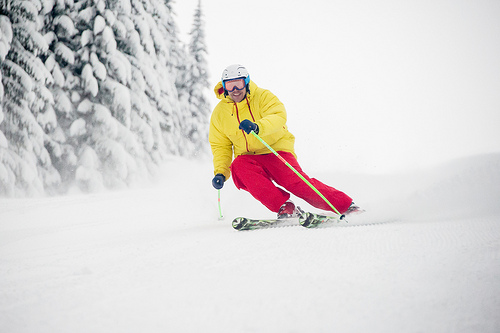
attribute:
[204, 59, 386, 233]
man — skier, standing, skiing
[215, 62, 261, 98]
helmet — white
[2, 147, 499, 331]
snow — white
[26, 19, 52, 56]
snow — white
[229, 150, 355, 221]
pants — red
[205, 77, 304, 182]
sweatshirt — yellow, hooded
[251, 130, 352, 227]
ski pole — neon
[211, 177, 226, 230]
ski pole — neon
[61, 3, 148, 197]
snow — white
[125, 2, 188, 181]
snow — white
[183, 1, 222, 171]
snow — white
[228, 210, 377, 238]
skis — white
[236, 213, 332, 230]
accents — green, black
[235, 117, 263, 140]
glove — navy blue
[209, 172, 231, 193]
glove — navy blue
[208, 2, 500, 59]
clouds — white